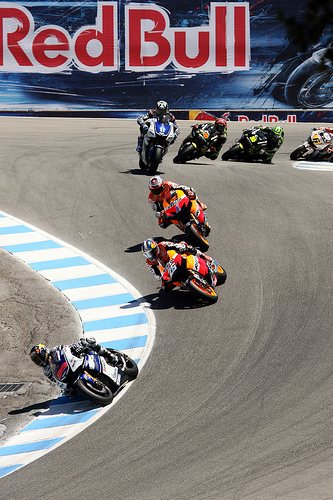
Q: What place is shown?
A: It is a road.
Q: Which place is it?
A: It is a road.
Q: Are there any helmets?
A: Yes, there is a helmet.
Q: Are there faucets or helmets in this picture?
A: Yes, there is a helmet.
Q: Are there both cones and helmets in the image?
A: No, there is a helmet but no cones.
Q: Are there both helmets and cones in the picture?
A: No, there is a helmet but no cones.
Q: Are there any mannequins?
A: No, there are no mannequins.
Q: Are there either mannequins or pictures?
A: No, there are no mannequins or pictures.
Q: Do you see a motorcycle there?
A: Yes, there is a motorcycle.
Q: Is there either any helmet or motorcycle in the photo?
A: Yes, there is a motorcycle.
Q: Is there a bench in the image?
A: No, there are no benches.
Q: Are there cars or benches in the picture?
A: No, there are no benches or cars.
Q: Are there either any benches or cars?
A: No, there are no benches or cars.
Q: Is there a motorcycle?
A: Yes, there is a motorcycle.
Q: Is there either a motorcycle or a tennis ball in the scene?
A: Yes, there is a motorcycle.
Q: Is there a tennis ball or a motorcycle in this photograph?
A: Yes, there is a motorcycle.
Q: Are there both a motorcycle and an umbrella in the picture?
A: No, there is a motorcycle but no umbrellas.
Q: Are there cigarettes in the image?
A: No, there are no cigarettes.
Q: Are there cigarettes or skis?
A: No, there are no cigarettes or skis.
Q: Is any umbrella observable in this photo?
A: No, there are no umbrellas.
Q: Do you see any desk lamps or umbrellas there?
A: No, there are no umbrellas or desk lamps.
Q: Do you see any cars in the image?
A: No, there are no cars.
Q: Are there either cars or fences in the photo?
A: No, there are no cars or fences.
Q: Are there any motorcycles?
A: Yes, there is a motorcycle.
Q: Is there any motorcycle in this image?
A: Yes, there is a motorcycle.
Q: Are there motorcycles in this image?
A: Yes, there is a motorcycle.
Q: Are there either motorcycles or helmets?
A: Yes, there is a motorcycle.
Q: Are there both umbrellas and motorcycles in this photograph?
A: No, there is a motorcycle but no umbrellas.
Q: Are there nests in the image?
A: No, there are no nests.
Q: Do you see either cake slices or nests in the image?
A: No, there are no nests or cake slices.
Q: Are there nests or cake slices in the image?
A: No, there are no nests or cake slices.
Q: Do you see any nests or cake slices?
A: No, there are no nests or cake slices.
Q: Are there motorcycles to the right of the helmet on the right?
A: Yes, there is a motorcycle to the right of the helmet.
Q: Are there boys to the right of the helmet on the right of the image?
A: No, there is a motorcycle to the right of the helmet.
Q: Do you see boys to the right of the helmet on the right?
A: No, there is a motorcycle to the right of the helmet.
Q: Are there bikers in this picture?
A: Yes, there is a biker.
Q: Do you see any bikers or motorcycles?
A: Yes, there is a biker.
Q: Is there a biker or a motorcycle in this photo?
A: Yes, there is a biker.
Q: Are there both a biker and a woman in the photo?
A: No, there is a biker but no women.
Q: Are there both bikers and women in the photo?
A: No, there is a biker but no women.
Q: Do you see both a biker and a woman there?
A: No, there is a biker but no women.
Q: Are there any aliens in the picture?
A: No, there are no aliens.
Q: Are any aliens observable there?
A: No, there are no aliens.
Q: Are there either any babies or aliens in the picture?
A: No, there are no aliens or babies.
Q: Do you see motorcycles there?
A: Yes, there is a motorcycle.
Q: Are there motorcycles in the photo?
A: Yes, there is a motorcycle.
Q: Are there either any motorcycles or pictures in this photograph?
A: Yes, there is a motorcycle.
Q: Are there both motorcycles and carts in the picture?
A: No, there is a motorcycle but no carts.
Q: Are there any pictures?
A: No, there are no pictures.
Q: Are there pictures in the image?
A: No, there are no pictures.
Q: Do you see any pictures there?
A: No, there are no pictures.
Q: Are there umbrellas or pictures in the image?
A: No, there are no pictures or umbrellas.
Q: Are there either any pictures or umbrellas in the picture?
A: No, there are no pictures or umbrellas.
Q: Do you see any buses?
A: No, there are no buses.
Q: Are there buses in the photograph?
A: No, there are no buses.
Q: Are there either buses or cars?
A: No, there are no buses or cars.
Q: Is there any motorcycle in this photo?
A: Yes, there is a motorcycle.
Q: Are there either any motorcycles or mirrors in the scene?
A: Yes, there is a motorcycle.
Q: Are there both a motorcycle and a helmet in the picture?
A: Yes, there are both a motorcycle and a helmet.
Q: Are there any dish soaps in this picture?
A: No, there are no dish soaps.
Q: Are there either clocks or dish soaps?
A: No, there are no dish soaps or clocks.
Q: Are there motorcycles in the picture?
A: Yes, there is a motorcycle.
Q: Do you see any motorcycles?
A: Yes, there is a motorcycle.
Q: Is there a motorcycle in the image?
A: Yes, there is a motorcycle.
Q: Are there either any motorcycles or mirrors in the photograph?
A: Yes, there is a motorcycle.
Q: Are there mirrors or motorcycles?
A: Yes, there is a motorcycle.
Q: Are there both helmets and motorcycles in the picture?
A: Yes, there are both a motorcycle and a helmet.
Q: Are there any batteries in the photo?
A: No, there are no batteries.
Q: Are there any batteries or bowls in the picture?
A: No, there are no batteries or bowls.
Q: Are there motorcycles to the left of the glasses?
A: Yes, there is a motorcycle to the left of the glasses.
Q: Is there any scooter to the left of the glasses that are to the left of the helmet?
A: No, there is a motorcycle to the left of the glasses.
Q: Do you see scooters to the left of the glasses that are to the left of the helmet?
A: No, there is a motorcycle to the left of the glasses.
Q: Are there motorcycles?
A: Yes, there is a motorcycle.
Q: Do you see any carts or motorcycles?
A: Yes, there is a motorcycle.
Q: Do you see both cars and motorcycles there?
A: No, there is a motorcycle but no cars.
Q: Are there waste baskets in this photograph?
A: No, there are no waste baskets.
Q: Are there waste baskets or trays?
A: No, there are no waste baskets or trays.